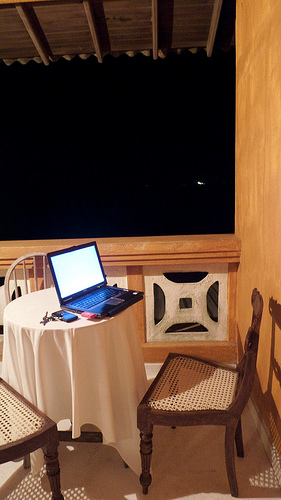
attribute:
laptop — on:
[45, 243, 140, 320]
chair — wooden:
[137, 279, 272, 495]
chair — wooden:
[4, 386, 55, 500]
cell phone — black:
[51, 308, 75, 324]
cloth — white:
[22, 339, 118, 402]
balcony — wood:
[245, 47, 270, 200]